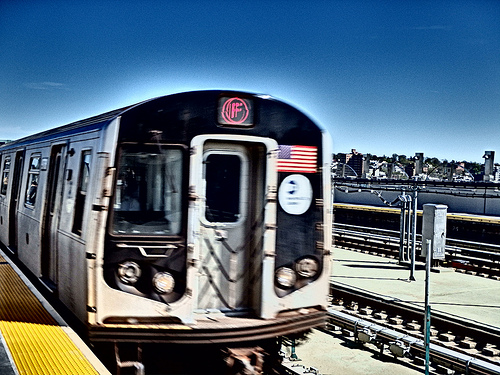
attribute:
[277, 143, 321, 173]
flag — red white, blue, american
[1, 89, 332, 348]
train — silver, black, gray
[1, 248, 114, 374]
platform — yellow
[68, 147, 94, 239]
window — passenger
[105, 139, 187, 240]
front window — clear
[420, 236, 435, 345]
sign post — gray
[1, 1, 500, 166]
sky — blue, clear, deep blue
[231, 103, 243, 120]
letter f — pink, red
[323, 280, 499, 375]
tracks — metal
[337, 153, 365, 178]
buildings — in background, in the distance